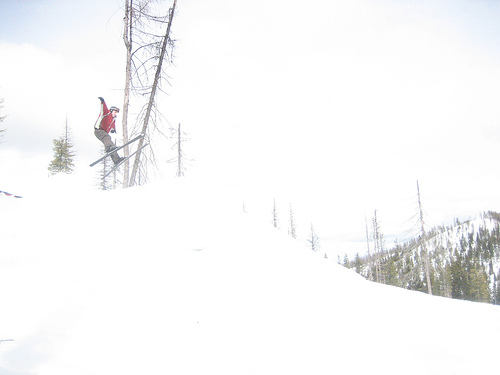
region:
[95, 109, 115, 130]
The red coat the skier is wearing.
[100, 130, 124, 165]
The pants the skier is wearing.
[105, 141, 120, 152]
The skier's left ski boot.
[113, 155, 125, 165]
The skier's right ski boot.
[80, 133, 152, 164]
The left ski on the skier's foot.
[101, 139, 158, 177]
The right ski on the skier's foot.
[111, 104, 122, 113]
The snow goggles on the skier's head.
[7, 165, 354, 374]
The snow hill the skier is jumping.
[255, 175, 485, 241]
The trees in the distance.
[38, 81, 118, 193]
The trees behind the skier.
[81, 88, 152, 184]
the skier in the air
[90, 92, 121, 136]
the arms of the skier stretched out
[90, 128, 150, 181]
the skies on the mans feet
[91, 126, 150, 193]
the skies stretched out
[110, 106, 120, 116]
the googles on the mans head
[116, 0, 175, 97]
the dead trees with no leaves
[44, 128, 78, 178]
the tree over the snowy hill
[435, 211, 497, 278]
the trees on the snowy hill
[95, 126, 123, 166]
the grey cargo pants on the skier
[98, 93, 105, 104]
the black glove on the hand of the man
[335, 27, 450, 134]
this is the sky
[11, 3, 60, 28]
the sky is blue in color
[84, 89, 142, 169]
this is a man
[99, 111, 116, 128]
this is a jacket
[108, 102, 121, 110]
this is a helmet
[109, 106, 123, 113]
the helmet is black in color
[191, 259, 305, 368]
this is the snow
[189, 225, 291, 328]
the snow is white in color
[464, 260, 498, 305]
this is a tree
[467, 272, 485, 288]
the tree is green in color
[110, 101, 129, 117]
Person wearing helmet on head.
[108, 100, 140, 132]
Helmet on person's head is black.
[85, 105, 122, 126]
Person wearing red coat.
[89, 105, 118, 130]
White strip on side of coat.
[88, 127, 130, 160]
Person wearing tan pants.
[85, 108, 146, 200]
Person wearing skis on feet.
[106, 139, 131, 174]
Person wearing dark colored boots.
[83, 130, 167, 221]
Person doing jump on skis.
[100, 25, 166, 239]
Large tree beside man.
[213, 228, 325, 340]
Ground is covered in white snow.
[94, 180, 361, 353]
mountain covered with snow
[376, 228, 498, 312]
pine trees in the snow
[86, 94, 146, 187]
a person playing with snow board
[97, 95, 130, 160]
a person wearing snowsuit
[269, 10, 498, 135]
blue sky with clouds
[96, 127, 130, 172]
a person wearing grey color pant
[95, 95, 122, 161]
a person trying to balance himself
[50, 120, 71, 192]
pine trees in the snow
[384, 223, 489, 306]
lot of pine trees in the snow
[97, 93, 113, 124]
a person lifting his hand up